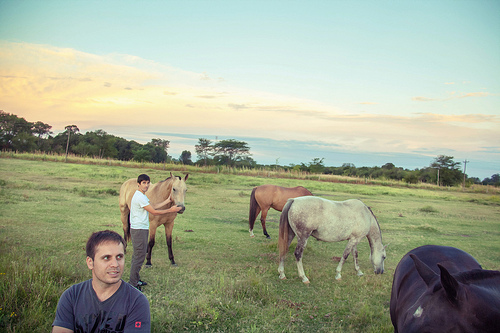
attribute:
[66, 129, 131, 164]
foliage — dark green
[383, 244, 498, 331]
horse — brown, in group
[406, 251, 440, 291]
ear — pointy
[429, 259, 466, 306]
ear — pointy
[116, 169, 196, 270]
horse — light brown, brown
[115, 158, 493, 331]
horses — in group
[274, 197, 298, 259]
tail — long, hairy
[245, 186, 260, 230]
tail — long, hairy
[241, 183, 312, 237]
horse — in group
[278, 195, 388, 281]
white/gray horse — white, grey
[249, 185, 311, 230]
horse — brown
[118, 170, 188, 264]
horse — in group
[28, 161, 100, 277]
field — green 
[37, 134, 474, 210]
grass — green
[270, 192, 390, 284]
horse — in group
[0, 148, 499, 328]
grass — green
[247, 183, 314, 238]
horse — brown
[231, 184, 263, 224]
tail — dark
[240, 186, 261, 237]
hair — long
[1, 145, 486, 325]
field — grassy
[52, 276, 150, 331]
shirt — blue